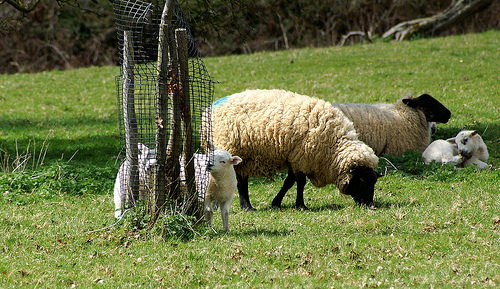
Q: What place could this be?
A: It is a field.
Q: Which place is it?
A: It is a field.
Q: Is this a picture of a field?
A: Yes, it is showing a field.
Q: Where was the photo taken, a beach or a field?
A: It was taken at a field.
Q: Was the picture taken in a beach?
A: No, the picture was taken in a field.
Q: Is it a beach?
A: No, it is a field.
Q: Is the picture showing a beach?
A: No, the picture is showing a field.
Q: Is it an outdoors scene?
A: Yes, it is outdoors.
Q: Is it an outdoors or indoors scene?
A: It is outdoors.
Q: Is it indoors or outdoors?
A: It is outdoors.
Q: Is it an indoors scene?
A: No, it is outdoors.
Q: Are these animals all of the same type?
A: Yes, all the animals are sheep.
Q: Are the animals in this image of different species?
A: No, all the animals are sheep.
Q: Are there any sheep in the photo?
A: Yes, there is a sheep.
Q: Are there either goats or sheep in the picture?
A: Yes, there is a sheep.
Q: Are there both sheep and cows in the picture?
A: No, there is a sheep but no cows.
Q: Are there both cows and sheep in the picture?
A: No, there is a sheep but no cows.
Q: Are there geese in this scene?
A: No, there are no geese.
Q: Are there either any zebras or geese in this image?
A: No, there are no geese or zebras.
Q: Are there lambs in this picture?
A: Yes, there is a lamb.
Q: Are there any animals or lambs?
A: Yes, there is a lamb.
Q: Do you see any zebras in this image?
A: No, there are no zebras.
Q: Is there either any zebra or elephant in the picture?
A: No, there are no zebras or elephants.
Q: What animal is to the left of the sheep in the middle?
A: The animal is a lamb.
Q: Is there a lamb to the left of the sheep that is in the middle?
A: Yes, there is a lamb to the left of the sheep.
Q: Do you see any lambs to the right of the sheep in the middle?
A: No, the lamb is to the left of the sheep.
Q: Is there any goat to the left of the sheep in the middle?
A: No, there is a lamb to the left of the sheep.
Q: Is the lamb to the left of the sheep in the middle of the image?
A: Yes, the lamb is to the left of the sheep.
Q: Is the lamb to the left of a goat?
A: No, the lamb is to the left of the sheep.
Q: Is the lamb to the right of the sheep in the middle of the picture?
A: No, the lamb is to the left of the sheep.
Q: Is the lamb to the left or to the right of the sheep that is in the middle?
A: The lamb is to the left of the sheep.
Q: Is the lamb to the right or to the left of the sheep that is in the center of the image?
A: The lamb is to the left of the sheep.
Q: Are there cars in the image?
A: No, there are no cars.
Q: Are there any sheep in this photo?
A: Yes, there is a sheep.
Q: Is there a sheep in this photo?
A: Yes, there is a sheep.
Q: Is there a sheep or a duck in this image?
A: Yes, there is a sheep.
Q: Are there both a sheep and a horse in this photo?
A: No, there is a sheep but no horses.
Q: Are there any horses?
A: No, there are no horses.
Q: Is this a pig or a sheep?
A: This is a sheep.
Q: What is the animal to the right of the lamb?
A: The animal is a sheep.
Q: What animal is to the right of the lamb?
A: The animal is a sheep.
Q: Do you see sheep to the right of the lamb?
A: Yes, there is a sheep to the right of the lamb.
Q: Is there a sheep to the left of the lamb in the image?
A: No, the sheep is to the right of the lamb.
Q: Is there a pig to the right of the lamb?
A: No, there is a sheep to the right of the lamb.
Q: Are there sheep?
A: Yes, there is a sheep.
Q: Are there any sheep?
A: Yes, there is a sheep.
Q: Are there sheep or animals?
A: Yes, there is a sheep.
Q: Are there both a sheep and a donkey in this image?
A: No, there is a sheep but no donkeys.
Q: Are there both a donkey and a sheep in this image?
A: No, there is a sheep but no donkeys.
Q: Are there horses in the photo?
A: No, there are no horses.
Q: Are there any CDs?
A: No, there are no cds.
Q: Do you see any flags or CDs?
A: No, there are no CDs or flags.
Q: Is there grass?
A: Yes, there is grass.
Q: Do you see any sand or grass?
A: Yes, there is grass.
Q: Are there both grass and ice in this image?
A: No, there is grass but no ice.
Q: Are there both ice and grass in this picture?
A: No, there is grass but no ice.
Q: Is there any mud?
A: No, there is no mud.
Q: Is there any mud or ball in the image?
A: No, there are no mud or balls.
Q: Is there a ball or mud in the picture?
A: No, there are no mud or balls.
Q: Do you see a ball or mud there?
A: No, there are no mud or balls.